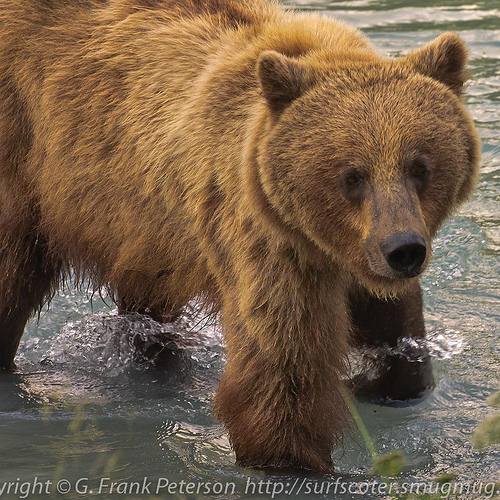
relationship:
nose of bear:
[387, 243, 426, 275] [1, 0, 481, 475]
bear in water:
[1, 0, 481, 475] [1, 0, 499, 499]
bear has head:
[1, 0, 481, 475] [258, 32, 477, 299]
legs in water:
[1, 237, 434, 475] [1, 0, 499, 499]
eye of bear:
[343, 172, 362, 186] [1, 0, 481, 475]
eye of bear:
[410, 163, 428, 177] [1, 0, 481, 475]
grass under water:
[37, 389, 126, 474] [1, 0, 499, 499]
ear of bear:
[258, 50, 321, 112] [1, 0, 481, 475]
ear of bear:
[406, 31, 467, 87] [1, 0, 481, 475]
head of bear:
[258, 32, 477, 299] [1, 0, 481, 475]